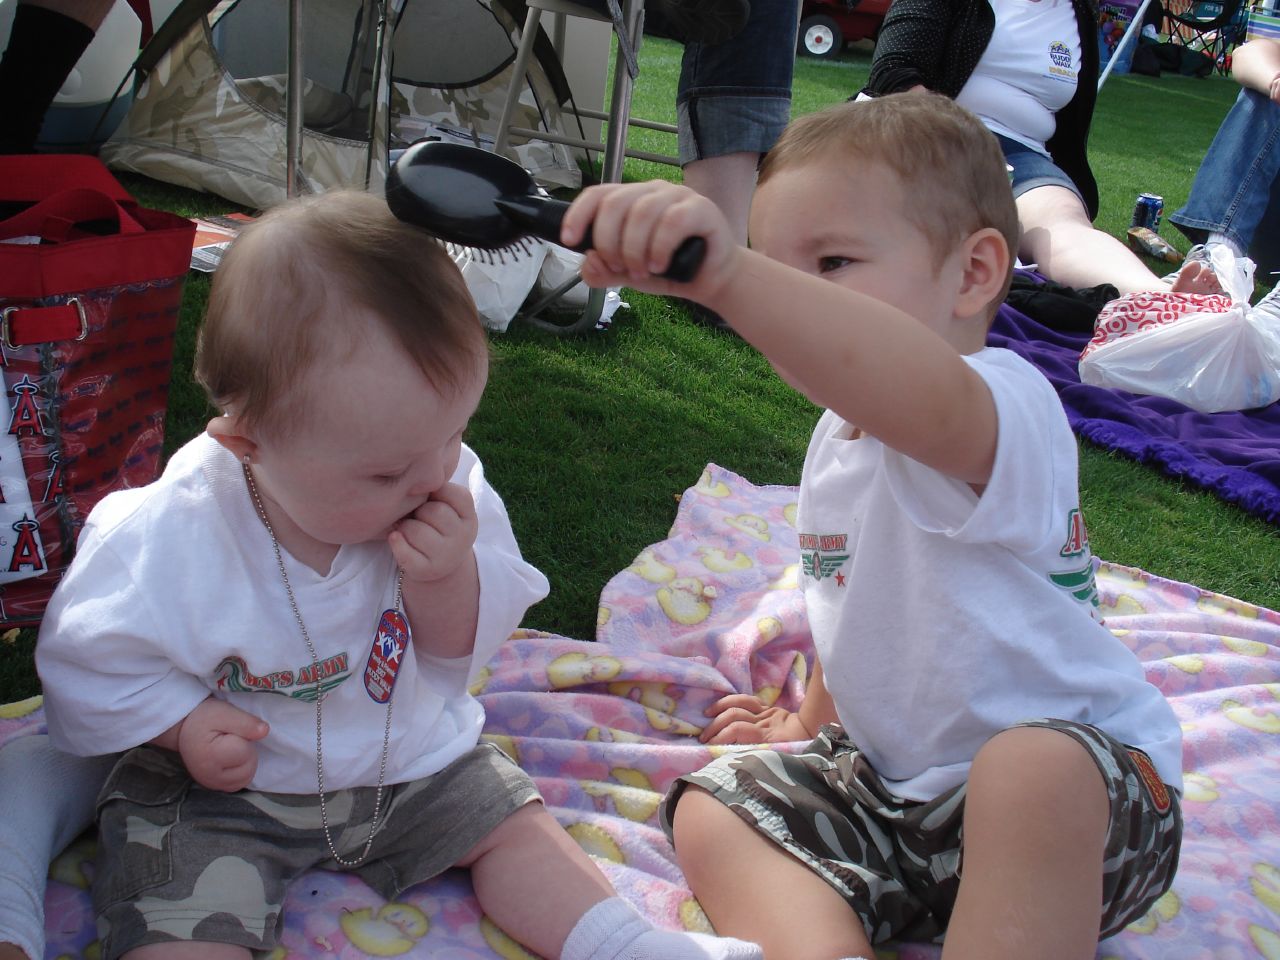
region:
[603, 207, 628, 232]
finger of the person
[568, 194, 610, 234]
finger of the person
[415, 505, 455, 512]
finger of the person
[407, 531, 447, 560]
finger of the person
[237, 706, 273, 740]
finger of the person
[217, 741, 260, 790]
finger of the person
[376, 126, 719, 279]
Black brush in a baby's hand.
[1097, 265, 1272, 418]
Red and white Target bag with a know in it.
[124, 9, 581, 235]
Camouflage tint on the ground.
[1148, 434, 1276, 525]
Purple cover lying on the ground.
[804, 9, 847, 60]
Small black wheel with white rims.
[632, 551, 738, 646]
Yellow shapes printed on purple throw.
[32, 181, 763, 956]
the baby wearing a white sock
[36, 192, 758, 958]
the baby wearing a long chain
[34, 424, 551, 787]
the shirt is white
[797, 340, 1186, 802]
the shirt is white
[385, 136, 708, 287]
the brush is black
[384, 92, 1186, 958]
the baby holding the black brush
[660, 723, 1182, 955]
the shorts are camo print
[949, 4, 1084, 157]
the shirt is white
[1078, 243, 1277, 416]
the red and white bag made of plastic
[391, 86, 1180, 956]
the baby holding the brush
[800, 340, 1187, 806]
the shirt is white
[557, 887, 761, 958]
the sock is white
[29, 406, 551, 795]
the shirt is white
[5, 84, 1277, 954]
the babies sitting on the blanket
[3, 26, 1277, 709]
the grass is green and lush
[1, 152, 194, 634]
the bag is red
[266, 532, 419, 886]
The necklace the baby has around its neck.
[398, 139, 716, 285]
The black brush the child is using to brush the baby's hair.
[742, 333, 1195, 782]
The white t-shirt the child on the right is wearing.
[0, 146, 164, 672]
The red bag behind the baby that is sitting down.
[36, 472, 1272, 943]
The pink and yellow blanket the kids are sitting on.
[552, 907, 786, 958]
The white sock the baby is wearing.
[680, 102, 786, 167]
The gray shorts the person standing in the distance is wearing.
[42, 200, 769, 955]
baby sitting on a pink blanket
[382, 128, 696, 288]
baby holding a black brush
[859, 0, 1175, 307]
lady sitting on a purple blanket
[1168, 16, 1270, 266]
lady sitting on a purple blanket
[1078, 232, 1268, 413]
white bag sitting on a purple blanket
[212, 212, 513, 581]
a young child with their hand in their mouth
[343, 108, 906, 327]
a young child holding a hair brush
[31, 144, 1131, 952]
two young children sitting on a blanket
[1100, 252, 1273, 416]
a white and red plastic bag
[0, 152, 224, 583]
a red bag on the ground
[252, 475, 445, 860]
a young child wearing a silver necklace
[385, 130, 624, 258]
a black hair brush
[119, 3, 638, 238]
a small tent set up on the ground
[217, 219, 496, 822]
baby boy sittin on the cloth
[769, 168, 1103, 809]
child whit a white shirt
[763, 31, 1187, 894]
boy sit in the cloth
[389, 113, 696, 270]
black comb in the left hand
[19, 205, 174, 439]
red bag in the corner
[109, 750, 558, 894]
gray and green short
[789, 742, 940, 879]
gray and green short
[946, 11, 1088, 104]
woman whit white shirt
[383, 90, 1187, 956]
child holding a black brush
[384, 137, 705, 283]
the brush is black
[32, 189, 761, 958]
baby in camo shorts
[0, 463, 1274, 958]
blanket with yellow duckies